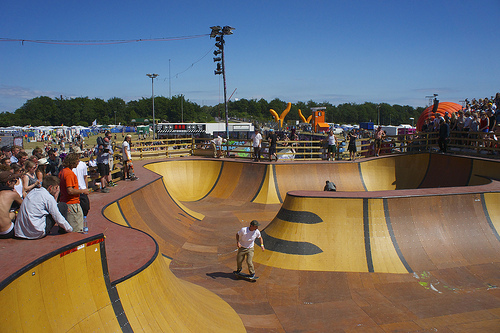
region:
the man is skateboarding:
[222, 214, 272, 302]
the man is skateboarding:
[207, 197, 298, 317]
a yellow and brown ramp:
[139, 142, 461, 325]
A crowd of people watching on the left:
[0, 143, 137, 258]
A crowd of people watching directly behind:
[196, 123, 379, 172]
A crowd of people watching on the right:
[352, 87, 491, 168]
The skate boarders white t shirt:
[234, 227, 259, 247]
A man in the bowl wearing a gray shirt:
[316, 178, 335, 195]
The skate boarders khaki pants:
[234, 240, 255, 274]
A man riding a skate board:
[232, 226, 260, 283]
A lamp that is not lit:
[205, 23, 236, 156]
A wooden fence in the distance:
[133, 133, 498, 169]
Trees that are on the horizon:
[23, 93, 487, 136]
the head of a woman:
[239, 208, 264, 245]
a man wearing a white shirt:
[227, 216, 282, 261]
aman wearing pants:
[231, 225, 286, 287]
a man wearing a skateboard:
[208, 198, 310, 285]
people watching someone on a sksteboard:
[16, 83, 124, 230]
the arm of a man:
[257, 233, 276, 255]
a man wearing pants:
[226, 237, 276, 282]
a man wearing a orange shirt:
[56, 148, 96, 203]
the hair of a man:
[48, 145, 99, 176]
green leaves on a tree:
[134, 71, 334, 126]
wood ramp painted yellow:
[258, 196, 407, 278]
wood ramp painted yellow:
[160, 160, 220, 205]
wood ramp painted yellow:
[116, 252, 250, 330]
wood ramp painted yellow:
[364, 154, 427, 189]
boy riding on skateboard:
[231, 221, 268, 283]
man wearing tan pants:
[235, 224, 266, 281]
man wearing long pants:
[228, 221, 268, 279]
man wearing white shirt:
[235, 222, 265, 284]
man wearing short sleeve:
[233, 219, 264, 281]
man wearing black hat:
[232, 219, 264, 281]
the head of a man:
[234, 200, 288, 241]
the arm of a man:
[229, 222, 246, 253]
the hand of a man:
[257, 232, 276, 260]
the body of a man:
[231, 210, 281, 257]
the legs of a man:
[226, 240, 271, 276]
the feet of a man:
[216, 258, 301, 278]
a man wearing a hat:
[241, 211, 269, 235]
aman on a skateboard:
[193, 178, 317, 301]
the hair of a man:
[36, 172, 64, 197]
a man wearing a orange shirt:
[43, 122, 101, 208]